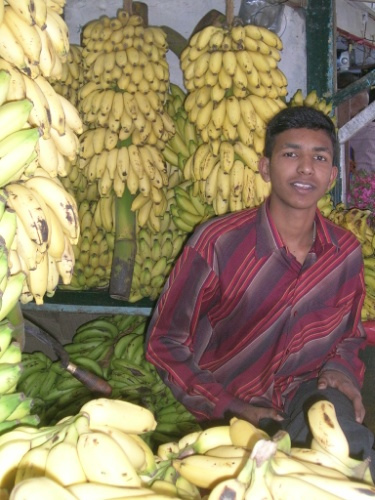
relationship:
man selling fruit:
[146, 105, 372, 462] [305, 396, 350, 458]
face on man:
[272, 131, 330, 207] [146, 105, 372, 462]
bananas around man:
[77, 5, 169, 302] [146, 105, 372, 462]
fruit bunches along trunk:
[82, 27, 277, 180] [101, 191, 139, 306]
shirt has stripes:
[149, 207, 360, 411] [222, 260, 279, 317]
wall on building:
[282, 15, 354, 89] [69, 2, 373, 132]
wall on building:
[0, 0, 375, 500] [9, 2, 374, 491]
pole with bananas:
[108, 182, 136, 301] [77, 7, 175, 232]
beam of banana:
[108, 2, 150, 299] [145, 56, 160, 86]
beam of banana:
[108, 2, 150, 299] [128, 85, 150, 115]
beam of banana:
[108, 2, 150, 299] [101, 118, 119, 152]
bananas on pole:
[77, 5, 169, 302] [112, 2, 146, 307]